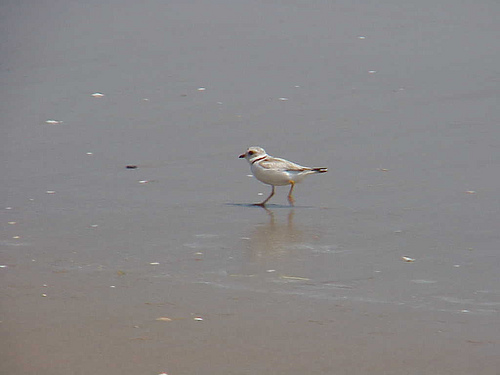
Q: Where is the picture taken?
A: The shore.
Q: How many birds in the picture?
A: One.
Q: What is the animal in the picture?
A: A bird.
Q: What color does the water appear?
A: Gray.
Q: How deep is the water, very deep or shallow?
A: Shallow.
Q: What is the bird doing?
A: Walking.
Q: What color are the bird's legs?
A: Orange.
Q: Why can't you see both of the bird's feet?
A: One is underwater.